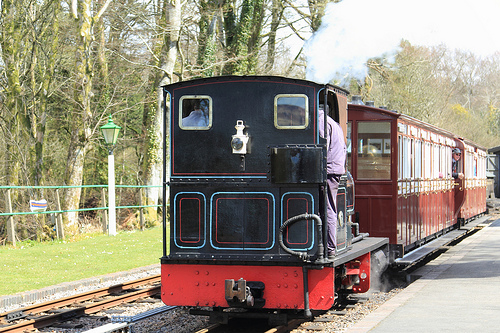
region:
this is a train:
[163, 80, 353, 273]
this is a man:
[327, 116, 342, 254]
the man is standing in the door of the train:
[327, 121, 342, 256]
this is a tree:
[66, 17, 93, 186]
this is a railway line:
[56, 298, 87, 313]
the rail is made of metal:
[83, 293, 118, 312]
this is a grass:
[41, 245, 88, 269]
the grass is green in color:
[31, 242, 124, 264]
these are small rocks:
[158, 315, 186, 328]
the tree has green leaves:
[235, 23, 250, 50]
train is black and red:
[144, 67, 376, 312]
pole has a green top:
[81, 110, 141, 242]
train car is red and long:
[346, 93, 493, 243]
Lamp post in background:
[92, 105, 126, 250]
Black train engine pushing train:
[140, 60, 395, 312]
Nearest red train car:
[346, 97, 456, 262]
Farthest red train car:
[441, 137, 498, 224]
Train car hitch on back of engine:
[212, 272, 264, 309]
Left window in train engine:
[174, 85, 214, 136]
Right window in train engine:
[270, 88, 317, 128]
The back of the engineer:
[313, 110, 348, 257]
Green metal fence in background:
[3, 172, 165, 239]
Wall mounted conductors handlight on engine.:
[219, 112, 259, 161]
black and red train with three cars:
[151, 67, 498, 316]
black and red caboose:
[143, 56, 397, 318]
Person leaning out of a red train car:
[345, 95, 467, 280]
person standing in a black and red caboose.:
[155, 70, 392, 320]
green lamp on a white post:
[97, 107, 129, 238]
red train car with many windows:
[346, 90, 466, 282]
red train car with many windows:
[457, 127, 490, 237]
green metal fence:
[4, 179, 160, 236]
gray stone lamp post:
[103, 148, 125, 235]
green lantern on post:
[97, 110, 120, 143]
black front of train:
[152, 62, 338, 259]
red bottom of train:
[157, 264, 333, 312]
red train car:
[347, 88, 453, 243]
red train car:
[454, 129, 491, 232]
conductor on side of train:
[320, 103, 340, 256]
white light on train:
[231, 110, 251, 159]